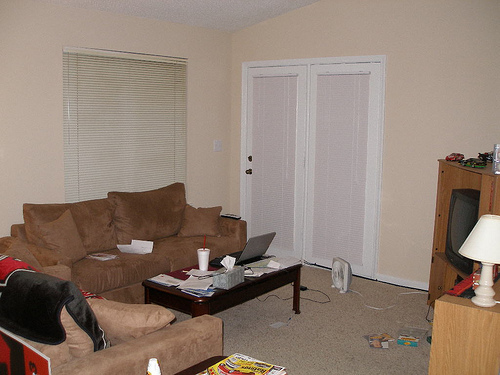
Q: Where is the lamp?
A: On the bookcase.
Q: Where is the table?
A: In front of the couch.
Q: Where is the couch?
A: In the living room.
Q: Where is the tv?
A: Corner.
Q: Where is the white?
A: Door.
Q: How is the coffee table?
A: Brown.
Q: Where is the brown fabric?
A: Couch.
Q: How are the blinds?
A: Closed.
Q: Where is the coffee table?
A: Front of couch.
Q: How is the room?
A: Messy.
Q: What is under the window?
A: A brown couch.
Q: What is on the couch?
A: Brown cushions.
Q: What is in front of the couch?
A: A coffee table.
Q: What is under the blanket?
A: A brown chair.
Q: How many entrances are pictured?
A: 1.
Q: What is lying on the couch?
A: Papers.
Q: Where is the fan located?
A: Floor.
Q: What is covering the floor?
A: Carpet.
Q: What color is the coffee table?
A: Brown.